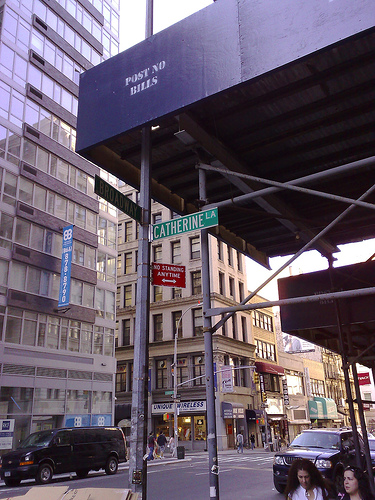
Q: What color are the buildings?
A: Brown.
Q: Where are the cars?
A: On the street.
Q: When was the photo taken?
A: Daytime.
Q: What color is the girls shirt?
A: White.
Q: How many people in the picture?
A: 3.